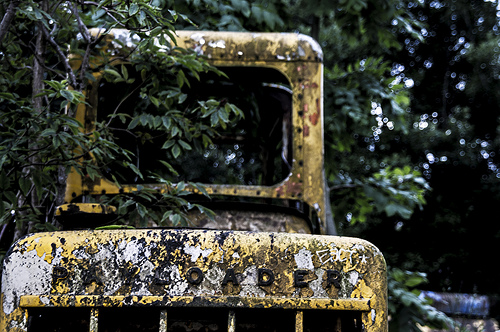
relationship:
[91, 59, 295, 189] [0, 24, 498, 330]
window on tractor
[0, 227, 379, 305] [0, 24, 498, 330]
paint on tractor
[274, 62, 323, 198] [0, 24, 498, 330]
rust on tractor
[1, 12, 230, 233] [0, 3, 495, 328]
tree branches in jungle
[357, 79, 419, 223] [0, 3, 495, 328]
leaves in jungle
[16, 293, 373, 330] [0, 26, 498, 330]
grill of payloader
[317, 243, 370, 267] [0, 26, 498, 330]
graffiti on front payloader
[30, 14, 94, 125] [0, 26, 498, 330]
tree branch hanging over front payloader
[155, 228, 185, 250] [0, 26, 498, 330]
marks on front payloader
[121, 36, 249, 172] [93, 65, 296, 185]
leaves in window opening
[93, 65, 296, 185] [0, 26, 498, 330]
window opening of payloader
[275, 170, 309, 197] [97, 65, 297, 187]
area near window opening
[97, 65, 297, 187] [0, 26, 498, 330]
window opening of payloader